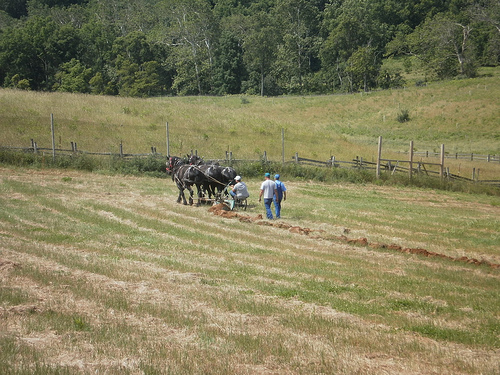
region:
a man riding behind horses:
[161, 153, 249, 208]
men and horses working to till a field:
[160, 150, 495, 275]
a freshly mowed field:
[2, 168, 172, 373]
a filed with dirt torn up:
[127, 218, 498, 374]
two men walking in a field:
[257, 171, 287, 222]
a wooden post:
[375, 135, 382, 177]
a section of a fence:
[2, 116, 167, 169]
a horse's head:
[164, 154, 176, 176]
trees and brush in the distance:
[0, 0, 490, 97]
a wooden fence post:
[406, 139, 414, 178]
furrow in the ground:
[390, 230, 497, 280]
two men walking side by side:
[255, 166, 287, 221]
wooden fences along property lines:
[355, 132, 495, 192]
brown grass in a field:
[31, 290, 216, 361]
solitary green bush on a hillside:
[380, 91, 432, 133]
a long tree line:
[10, 0, 340, 100]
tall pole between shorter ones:
[25, 106, 85, 158]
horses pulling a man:
[160, 146, 255, 217]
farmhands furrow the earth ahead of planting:
[155, 136, 310, 236]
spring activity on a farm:
[75, 100, 480, 290]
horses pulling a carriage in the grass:
[159, 142, 255, 217]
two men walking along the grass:
[251, 165, 300, 221]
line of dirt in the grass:
[219, 200, 478, 300]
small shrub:
[396, 106, 417, 126]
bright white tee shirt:
[258, 179, 278, 199]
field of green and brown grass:
[9, 163, 499, 373]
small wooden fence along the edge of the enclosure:
[11, 136, 461, 191]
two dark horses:
[159, 150, 235, 205]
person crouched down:
[226, 175, 253, 208]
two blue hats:
[261, 164, 283, 181]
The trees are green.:
[75, 8, 357, 73]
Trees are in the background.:
[86, 19, 263, 69]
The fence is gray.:
[321, 147, 488, 189]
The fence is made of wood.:
[331, 138, 455, 190]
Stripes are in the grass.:
[132, 284, 304, 371]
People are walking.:
[248, 156, 303, 230]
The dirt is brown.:
[323, 223, 495, 280]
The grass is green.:
[102, 252, 345, 352]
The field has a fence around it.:
[3, 130, 449, 182]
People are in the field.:
[204, 157, 347, 246]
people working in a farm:
[143, 133, 304, 226]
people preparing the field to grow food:
[132, 140, 484, 302]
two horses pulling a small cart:
[150, 140, 260, 210]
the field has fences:
[10, 105, 495, 175]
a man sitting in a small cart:
[220, 170, 252, 213]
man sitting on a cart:
[217, 176, 255, 213]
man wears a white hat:
[219, 170, 249, 210]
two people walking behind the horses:
[250, 167, 293, 229]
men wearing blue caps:
[252, 162, 289, 223]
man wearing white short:
[253, 169, 278, 217]